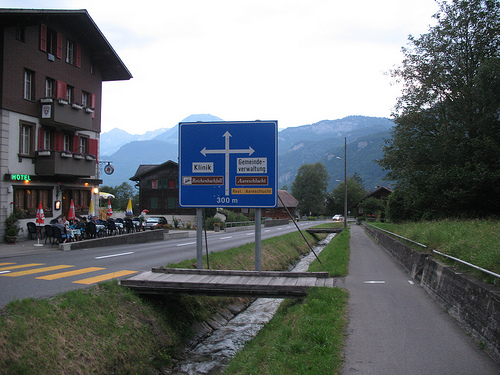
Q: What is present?
A: Trees.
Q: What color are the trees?
A: Green.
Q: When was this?
A: Daytime.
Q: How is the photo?
A: Clear.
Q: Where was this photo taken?
A: In a city.